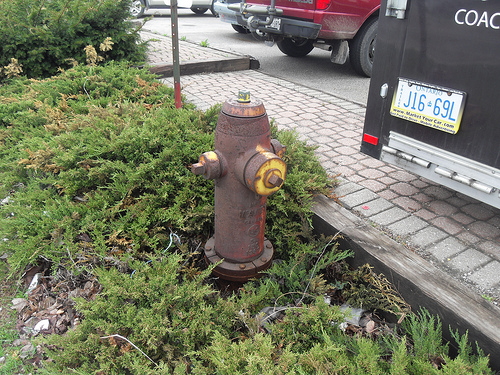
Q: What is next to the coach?
A: A fire hydrant.